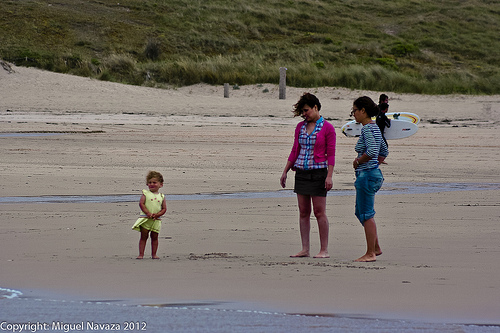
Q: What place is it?
A: It is a beach.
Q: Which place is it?
A: It is a beach.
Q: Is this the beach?
A: Yes, it is the beach.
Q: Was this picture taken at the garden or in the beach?
A: It was taken at the beach.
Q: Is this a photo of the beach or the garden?
A: It is showing the beach.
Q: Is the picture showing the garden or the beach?
A: It is showing the beach.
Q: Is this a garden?
A: No, it is a beach.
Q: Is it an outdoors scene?
A: Yes, it is outdoors.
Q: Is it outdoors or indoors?
A: It is outdoors.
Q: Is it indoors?
A: No, it is outdoors.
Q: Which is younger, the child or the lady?
A: The child is younger than the lady.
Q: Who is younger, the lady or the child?
A: The child is younger than the lady.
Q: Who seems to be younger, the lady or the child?
A: The child is younger than the lady.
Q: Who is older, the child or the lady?
A: The lady is older than the child.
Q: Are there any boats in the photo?
A: No, there are no boats.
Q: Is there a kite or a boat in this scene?
A: No, there are no boats or kites.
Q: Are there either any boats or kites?
A: No, there are no boats or kites.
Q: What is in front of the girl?
A: The ocean is in front of the girl.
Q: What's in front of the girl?
A: The ocean is in front of the girl.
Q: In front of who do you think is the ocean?
A: The ocean is in front of the girl.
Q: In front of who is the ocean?
A: The ocean is in front of the girl.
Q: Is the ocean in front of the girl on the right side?
A: Yes, the ocean is in front of the girl.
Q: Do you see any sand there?
A: Yes, there is sand.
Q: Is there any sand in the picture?
A: Yes, there is sand.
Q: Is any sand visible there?
A: Yes, there is sand.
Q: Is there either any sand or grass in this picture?
A: Yes, there is sand.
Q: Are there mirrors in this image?
A: No, there are no mirrors.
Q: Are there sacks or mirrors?
A: No, there are no mirrors or sacks.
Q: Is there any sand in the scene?
A: Yes, there is sand.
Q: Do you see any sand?
A: Yes, there is sand.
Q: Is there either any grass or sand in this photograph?
A: Yes, there is sand.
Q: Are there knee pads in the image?
A: No, there are no knee pads.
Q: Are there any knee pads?
A: No, there are no knee pads.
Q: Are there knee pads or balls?
A: No, there are no knee pads or balls.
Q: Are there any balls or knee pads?
A: No, there are no knee pads or balls.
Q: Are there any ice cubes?
A: No, there are no ice cubes.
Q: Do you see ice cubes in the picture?
A: No, there are no ice cubes.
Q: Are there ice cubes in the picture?
A: No, there are no ice cubes.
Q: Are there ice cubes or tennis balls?
A: No, there are no ice cubes or tennis balls.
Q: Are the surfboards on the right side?
A: Yes, the surfboards are on the right of the image.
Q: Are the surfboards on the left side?
A: No, the surfboards are on the right of the image.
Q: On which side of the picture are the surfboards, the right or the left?
A: The surfboards are on the right of the image.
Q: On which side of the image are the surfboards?
A: The surfboards are on the right of the image.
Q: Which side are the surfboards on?
A: The surfboards are on the right of the image.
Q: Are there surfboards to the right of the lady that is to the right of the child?
A: Yes, there are surfboards to the right of the lady.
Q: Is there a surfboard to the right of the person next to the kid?
A: Yes, there are surfboards to the right of the lady.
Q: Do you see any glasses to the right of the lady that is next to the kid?
A: No, there are surfboards to the right of the lady.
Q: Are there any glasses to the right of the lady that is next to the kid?
A: No, there are surfboards to the right of the lady.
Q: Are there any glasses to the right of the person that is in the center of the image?
A: No, there are surfboards to the right of the lady.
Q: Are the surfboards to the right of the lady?
A: Yes, the surfboards are to the right of the lady.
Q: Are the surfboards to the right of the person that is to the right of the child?
A: Yes, the surfboards are to the right of the lady.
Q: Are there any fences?
A: No, there are no fences.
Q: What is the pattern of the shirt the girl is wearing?
A: The shirt is striped.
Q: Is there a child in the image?
A: Yes, there is a child.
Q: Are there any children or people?
A: Yes, there is a child.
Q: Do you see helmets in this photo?
A: No, there are no helmets.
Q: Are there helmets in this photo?
A: No, there are no helmets.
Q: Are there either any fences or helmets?
A: No, there are no helmets or fences.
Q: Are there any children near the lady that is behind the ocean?
A: Yes, there is a child near the lady.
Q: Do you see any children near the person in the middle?
A: Yes, there is a child near the lady.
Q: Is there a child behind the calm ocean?
A: Yes, there is a child behind the ocean.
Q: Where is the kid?
A: The kid is on the beach.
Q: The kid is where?
A: The kid is on the beach.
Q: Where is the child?
A: The kid is on the beach.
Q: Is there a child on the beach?
A: Yes, there is a child on the beach.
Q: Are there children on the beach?
A: Yes, there is a child on the beach.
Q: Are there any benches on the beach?
A: No, there is a child on the beach.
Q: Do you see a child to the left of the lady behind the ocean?
A: Yes, there is a child to the left of the lady.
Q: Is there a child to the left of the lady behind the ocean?
A: Yes, there is a child to the left of the lady.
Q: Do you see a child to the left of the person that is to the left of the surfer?
A: Yes, there is a child to the left of the lady.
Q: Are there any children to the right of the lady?
A: No, the child is to the left of the lady.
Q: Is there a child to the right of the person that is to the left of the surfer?
A: No, the child is to the left of the lady.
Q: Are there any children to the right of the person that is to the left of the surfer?
A: No, the child is to the left of the lady.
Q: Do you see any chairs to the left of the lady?
A: No, there is a child to the left of the lady.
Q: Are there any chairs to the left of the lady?
A: No, there is a child to the left of the lady.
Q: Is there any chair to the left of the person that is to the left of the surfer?
A: No, there is a child to the left of the lady.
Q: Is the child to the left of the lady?
A: Yes, the child is to the left of the lady.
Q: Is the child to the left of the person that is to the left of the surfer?
A: Yes, the child is to the left of the lady.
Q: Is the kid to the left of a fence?
A: No, the kid is to the left of the lady.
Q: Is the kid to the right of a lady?
A: No, the kid is to the left of a lady.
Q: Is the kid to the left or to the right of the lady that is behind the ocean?
A: The kid is to the left of the lady.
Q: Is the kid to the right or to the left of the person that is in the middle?
A: The kid is to the left of the lady.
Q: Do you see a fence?
A: No, there are no fences.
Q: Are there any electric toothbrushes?
A: No, there are no electric toothbrushes.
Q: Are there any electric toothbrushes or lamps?
A: No, there are no electric toothbrushes or lamps.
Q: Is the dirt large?
A: Yes, the dirt is large.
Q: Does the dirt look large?
A: Yes, the dirt is large.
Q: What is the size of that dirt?
A: The dirt is large.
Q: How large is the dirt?
A: The dirt is large.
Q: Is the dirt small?
A: No, the dirt is large.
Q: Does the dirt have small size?
A: No, the dirt is large.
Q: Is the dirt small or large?
A: The dirt is large.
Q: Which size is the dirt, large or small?
A: The dirt is large.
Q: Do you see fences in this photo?
A: No, there are no fences.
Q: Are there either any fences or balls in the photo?
A: No, there are no fences or balls.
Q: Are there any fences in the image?
A: No, there are no fences.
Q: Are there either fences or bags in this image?
A: No, there are no fences or bags.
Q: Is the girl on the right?
A: Yes, the girl is on the right of the image.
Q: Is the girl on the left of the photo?
A: No, the girl is on the right of the image.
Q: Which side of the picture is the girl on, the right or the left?
A: The girl is on the right of the image.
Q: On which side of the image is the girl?
A: The girl is on the right of the image.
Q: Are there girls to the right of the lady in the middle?
A: Yes, there is a girl to the right of the lady.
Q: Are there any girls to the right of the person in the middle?
A: Yes, there is a girl to the right of the lady.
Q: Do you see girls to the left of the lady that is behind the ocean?
A: No, the girl is to the right of the lady.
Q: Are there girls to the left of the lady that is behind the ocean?
A: No, the girl is to the right of the lady.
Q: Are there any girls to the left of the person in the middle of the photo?
A: No, the girl is to the right of the lady.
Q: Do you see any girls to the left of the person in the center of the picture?
A: No, the girl is to the right of the lady.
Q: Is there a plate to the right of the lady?
A: No, there is a girl to the right of the lady.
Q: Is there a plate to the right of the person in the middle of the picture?
A: No, there is a girl to the right of the lady.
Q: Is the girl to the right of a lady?
A: Yes, the girl is to the right of a lady.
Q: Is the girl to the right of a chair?
A: No, the girl is to the right of a lady.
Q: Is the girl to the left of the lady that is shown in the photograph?
A: No, the girl is to the right of the lady.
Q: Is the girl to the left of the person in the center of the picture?
A: No, the girl is to the right of the lady.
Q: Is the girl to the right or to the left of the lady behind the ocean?
A: The girl is to the right of the lady.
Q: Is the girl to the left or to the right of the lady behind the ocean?
A: The girl is to the right of the lady.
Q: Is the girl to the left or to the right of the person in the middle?
A: The girl is to the right of the lady.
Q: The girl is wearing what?
A: The girl is wearing a shirt.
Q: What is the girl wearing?
A: The girl is wearing a shirt.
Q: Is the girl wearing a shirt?
A: Yes, the girl is wearing a shirt.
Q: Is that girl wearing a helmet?
A: No, the girl is wearing a shirt.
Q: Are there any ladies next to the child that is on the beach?
A: Yes, there is a lady next to the kid.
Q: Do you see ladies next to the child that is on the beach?
A: Yes, there is a lady next to the kid.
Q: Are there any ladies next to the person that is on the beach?
A: Yes, there is a lady next to the kid.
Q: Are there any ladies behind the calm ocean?
A: Yes, there is a lady behind the ocean.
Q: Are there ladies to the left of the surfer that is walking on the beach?
A: Yes, there is a lady to the left of the surfer.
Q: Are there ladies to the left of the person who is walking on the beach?
A: Yes, there is a lady to the left of the surfer.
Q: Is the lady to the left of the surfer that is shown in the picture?
A: Yes, the lady is to the left of the surfer.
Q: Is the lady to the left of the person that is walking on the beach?
A: Yes, the lady is to the left of the surfer.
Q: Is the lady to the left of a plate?
A: No, the lady is to the left of the surfer.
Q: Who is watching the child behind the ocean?
A: The lady is watching the kid.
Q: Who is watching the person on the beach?
A: The lady is watching the kid.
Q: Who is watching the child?
A: The lady is watching the kid.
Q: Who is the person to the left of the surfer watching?
A: The lady is watching the child.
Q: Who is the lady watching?
A: The lady is watching the child.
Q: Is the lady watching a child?
A: Yes, the lady is watching a child.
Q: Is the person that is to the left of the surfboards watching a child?
A: Yes, the lady is watching a child.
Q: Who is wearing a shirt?
A: The lady is wearing a shirt.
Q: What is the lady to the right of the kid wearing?
A: The lady is wearing a shirt.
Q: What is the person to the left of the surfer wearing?
A: The lady is wearing a shirt.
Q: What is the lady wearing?
A: The lady is wearing a shirt.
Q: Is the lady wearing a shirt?
A: Yes, the lady is wearing a shirt.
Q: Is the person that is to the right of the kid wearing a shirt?
A: Yes, the lady is wearing a shirt.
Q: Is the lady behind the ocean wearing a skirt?
A: No, the lady is wearing a shirt.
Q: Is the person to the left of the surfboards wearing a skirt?
A: No, the lady is wearing a shirt.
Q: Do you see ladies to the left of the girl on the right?
A: Yes, there is a lady to the left of the girl.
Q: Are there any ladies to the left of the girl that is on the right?
A: Yes, there is a lady to the left of the girl.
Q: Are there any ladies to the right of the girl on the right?
A: No, the lady is to the left of the girl.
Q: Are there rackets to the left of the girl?
A: No, there is a lady to the left of the girl.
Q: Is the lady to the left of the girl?
A: Yes, the lady is to the left of the girl.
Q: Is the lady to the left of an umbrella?
A: No, the lady is to the left of the girl.